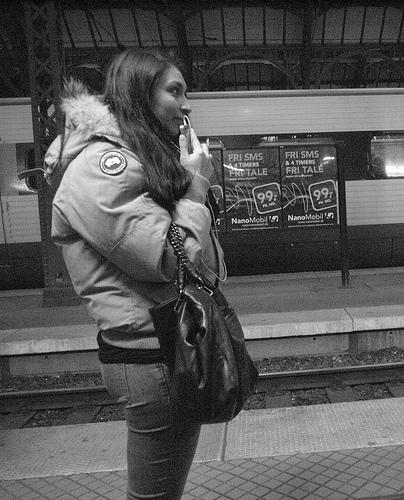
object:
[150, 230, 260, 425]
purse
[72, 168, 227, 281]
arm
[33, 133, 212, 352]
coat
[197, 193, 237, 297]
jack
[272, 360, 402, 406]
tracks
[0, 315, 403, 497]
ground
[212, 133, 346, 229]
advertisement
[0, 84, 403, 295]
train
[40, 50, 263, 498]
girl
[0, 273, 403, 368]
platform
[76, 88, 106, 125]
fur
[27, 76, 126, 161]
hood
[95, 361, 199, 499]
jeans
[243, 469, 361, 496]
tiles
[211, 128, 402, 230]
window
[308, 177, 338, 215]
99 cents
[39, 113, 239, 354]
jacket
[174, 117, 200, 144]
cellphone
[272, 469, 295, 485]
pattern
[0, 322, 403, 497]
sidewalk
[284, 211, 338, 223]
words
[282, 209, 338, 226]
nano mobile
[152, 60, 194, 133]
face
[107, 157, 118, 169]
square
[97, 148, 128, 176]
logo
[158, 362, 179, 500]
crease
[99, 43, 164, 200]
hair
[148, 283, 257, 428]
bag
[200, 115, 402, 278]
background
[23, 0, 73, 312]
beam